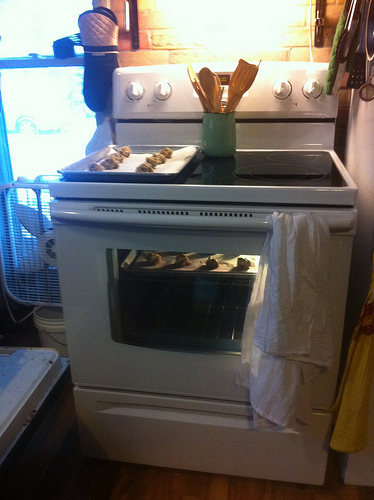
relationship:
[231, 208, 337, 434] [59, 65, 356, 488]
towel hangs on stove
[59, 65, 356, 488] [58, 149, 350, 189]
stove has surface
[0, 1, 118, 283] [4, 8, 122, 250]
window transmitting light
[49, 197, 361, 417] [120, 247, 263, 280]
oven contains a tray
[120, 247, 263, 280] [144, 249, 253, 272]
tray holds dough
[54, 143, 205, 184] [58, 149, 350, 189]
top tray on surface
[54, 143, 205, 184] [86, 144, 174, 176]
top tray holds top dough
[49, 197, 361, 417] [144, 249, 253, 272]
oven contains dough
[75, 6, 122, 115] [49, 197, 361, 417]
mitt for oven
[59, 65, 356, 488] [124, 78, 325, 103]
stove has knobs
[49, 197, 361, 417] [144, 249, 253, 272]
oven cooks dough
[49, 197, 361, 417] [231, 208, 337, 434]
oven holds towel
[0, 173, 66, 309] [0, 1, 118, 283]
box fan in front of window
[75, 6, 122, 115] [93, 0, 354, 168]
mitt hangs from brick wall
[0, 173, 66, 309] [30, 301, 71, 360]
box fan sits on pail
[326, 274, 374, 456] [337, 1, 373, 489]
handtowel hangs from cabinet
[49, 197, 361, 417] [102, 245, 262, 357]
oven has a glass window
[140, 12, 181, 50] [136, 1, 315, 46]
bricks on wall